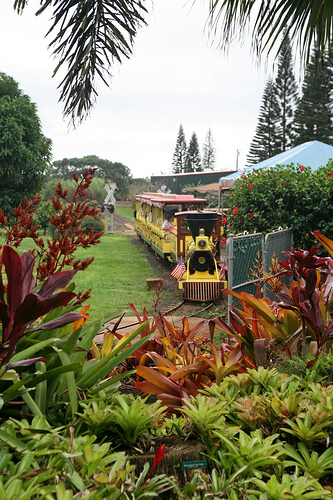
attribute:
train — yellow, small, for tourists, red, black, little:
[132, 189, 230, 306]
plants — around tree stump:
[0, 165, 332, 500]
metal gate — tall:
[225, 221, 266, 339]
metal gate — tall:
[262, 224, 296, 309]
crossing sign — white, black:
[100, 182, 119, 207]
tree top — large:
[220, 155, 331, 254]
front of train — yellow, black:
[175, 210, 229, 302]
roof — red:
[134, 190, 209, 208]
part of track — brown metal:
[157, 299, 216, 325]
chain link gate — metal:
[226, 226, 296, 341]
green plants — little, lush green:
[0, 314, 331, 499]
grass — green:
[0, 233, 161, 329]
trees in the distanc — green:
[44, 122, 217, 201]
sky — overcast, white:
[0, 0, 331, 180]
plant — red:
[0, 164, 108, 286]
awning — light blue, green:
[217, 139, 331, 194]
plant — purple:
[0, 244, 87, 373]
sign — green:
[178, 459, 207, 471]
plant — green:
[0, 307, 157, 429]